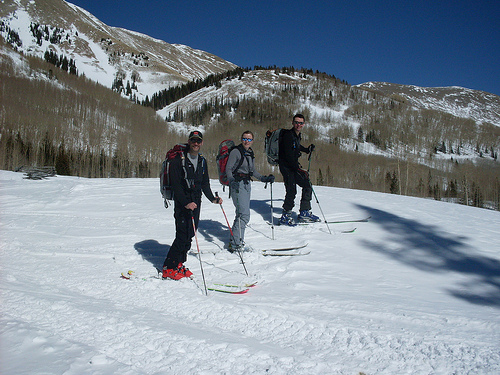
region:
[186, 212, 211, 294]
pole used for skiing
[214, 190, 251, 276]
pole used for skiing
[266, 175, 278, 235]
pole used for skiing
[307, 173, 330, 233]
pole used for skiing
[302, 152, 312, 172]
pole used for skiing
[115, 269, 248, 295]
ski covered with snow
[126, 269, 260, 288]
ski covered with snow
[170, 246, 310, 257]
ski covered with snow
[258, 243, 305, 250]
ski covered with snow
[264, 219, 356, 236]
ski covered with snow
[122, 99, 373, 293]
the men on skies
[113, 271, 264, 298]
the skies in the snow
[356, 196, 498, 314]
the tree shadow on the snow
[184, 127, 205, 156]
the hat on the ehad of the man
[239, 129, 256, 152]
the glasses on the face of the man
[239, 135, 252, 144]
the blue lens of the glasses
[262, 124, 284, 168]
the grey pack on the back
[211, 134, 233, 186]
the red backpack on the man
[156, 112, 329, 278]
three people on a ski hill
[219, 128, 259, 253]
woman is standing in between two men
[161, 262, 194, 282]
red ski boots the man is wearing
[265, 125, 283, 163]
black backpack on man's back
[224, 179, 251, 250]
gray pants the woman is wearing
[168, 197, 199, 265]
black pants man is wearing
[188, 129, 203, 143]
black cap man is wearing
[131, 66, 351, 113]
tall trees in the background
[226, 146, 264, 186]
gray jacket the woman is wearing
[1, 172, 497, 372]
white snow on the ground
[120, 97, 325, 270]
people on the snow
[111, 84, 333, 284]
people on the snow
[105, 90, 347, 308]
people on the snow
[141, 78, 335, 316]
people on the snow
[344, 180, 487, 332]
shadow on the snow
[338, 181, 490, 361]
shadow on the snow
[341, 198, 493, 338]
shadow on the snow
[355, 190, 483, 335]
shadow on the snow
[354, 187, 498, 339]
shadow on the snow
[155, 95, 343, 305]
three people on skiis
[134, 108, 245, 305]
man wearing skiing gear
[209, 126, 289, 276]
man wearing skiing gear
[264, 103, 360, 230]
man wearing skiing gear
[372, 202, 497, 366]
shadow of tall tree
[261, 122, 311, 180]
man wearing a backpack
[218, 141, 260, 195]
man wearing a backpack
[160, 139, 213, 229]
man wearing a backpack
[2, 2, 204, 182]
snowy mountain range in back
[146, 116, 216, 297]
man skiing on mountain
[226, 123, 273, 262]
man skiing on mountain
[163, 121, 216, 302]
man preparing to ski in white snow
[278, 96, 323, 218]
man preparing to ski in white snow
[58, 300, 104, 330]
white snow on hill side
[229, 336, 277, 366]
white snow on hill side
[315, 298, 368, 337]
white snow on hill side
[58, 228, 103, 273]
white snow on hill side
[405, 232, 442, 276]
white snow on hill side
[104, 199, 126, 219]
white snow on hill side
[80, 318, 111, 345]
white snow on hill side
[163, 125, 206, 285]
man wearing red snow boots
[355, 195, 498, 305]
tree shadow on the snow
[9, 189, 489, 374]
tracks in the snow